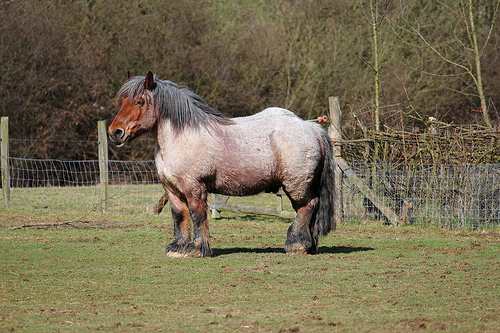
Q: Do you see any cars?
A: No, there are no cars.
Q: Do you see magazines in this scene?
A: No, there are no magazines.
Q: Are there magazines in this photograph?
A: No, there are no magazines.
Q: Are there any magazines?
A: No, there are no magazines.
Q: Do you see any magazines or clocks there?
A: No, there are no magazines or clocks.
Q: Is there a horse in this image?
A: Yes, there is a horse.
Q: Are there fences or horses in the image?
A: Yes, there is a horse.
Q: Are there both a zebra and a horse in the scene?
A: No, there is a horse but no zebras.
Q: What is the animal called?
A: The animal is a horse.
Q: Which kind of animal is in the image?
A: The animal is a horse.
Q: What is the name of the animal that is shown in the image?
A: The animal is a horse.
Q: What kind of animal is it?
A: The animal is a horse.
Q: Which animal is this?
A: This is a horse.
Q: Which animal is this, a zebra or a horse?
A: This is a horse.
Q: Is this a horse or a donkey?
A: This is a horse.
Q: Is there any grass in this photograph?
A: Yes, there is grass.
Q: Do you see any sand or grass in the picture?
A: Yes, there is grass.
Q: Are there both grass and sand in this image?
A: No, there is grass but no sand.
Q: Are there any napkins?
A: No, there are no napkins.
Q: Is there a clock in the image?
A: No, there are no clocks.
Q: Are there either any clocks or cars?
A: No, there are no clocks or cars.